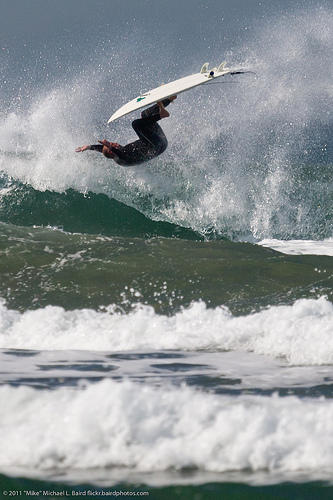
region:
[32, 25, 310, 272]
A man and a surboard falling from a tall wave.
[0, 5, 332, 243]
A large crashing wave.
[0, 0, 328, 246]
Water spraying in all directions.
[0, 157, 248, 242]
A wave tunnel forming.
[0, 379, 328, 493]
A wave rolling onto the shore.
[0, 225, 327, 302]
Choppy water between the waves.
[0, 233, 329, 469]
White water on the waves.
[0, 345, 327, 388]
Foam on the surface of the water.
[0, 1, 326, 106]
Blue skies above the water.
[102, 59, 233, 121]
An upside down surfboard falling from a wave.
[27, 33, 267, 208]
Man surfing in the ocean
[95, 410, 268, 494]
Foam in the water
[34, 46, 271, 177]
the surfboard is flipped upside down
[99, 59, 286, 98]
Surfboard is white and long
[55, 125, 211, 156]
the surfer is bald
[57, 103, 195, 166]
The surfer is wearing a wetsuit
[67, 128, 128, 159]
The man has his arm's outstretched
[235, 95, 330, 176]
Water is spraying from ocean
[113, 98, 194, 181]
Man's knees are bent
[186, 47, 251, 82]
Fins on bottom of surfboard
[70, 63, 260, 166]
A surfboarder is doing a flip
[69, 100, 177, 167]
The surfboarder is upside down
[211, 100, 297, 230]
The spray of the water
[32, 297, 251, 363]
Waves crashing against each other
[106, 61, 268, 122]
The bottom of the surfboard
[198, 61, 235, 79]
Talons on a surfboard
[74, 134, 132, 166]
The man's arms are outstretched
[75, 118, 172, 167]
The man's wetsuit is black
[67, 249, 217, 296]
The waves are sea green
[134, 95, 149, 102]
A green design on the surfboard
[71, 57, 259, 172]
man surfing in ocean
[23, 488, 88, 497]
name of photographer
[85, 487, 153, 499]
flickr web address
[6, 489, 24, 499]
numerical photograph year stamp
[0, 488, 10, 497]
white print copyright symbol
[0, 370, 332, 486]
white wave in ocean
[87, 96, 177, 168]
black wet suit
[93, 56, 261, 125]
white surfboard flipping over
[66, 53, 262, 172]
person crashing on a wave in the ocean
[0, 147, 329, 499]
green and blue ocean water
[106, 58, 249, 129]
white surfboard over man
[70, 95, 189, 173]
manin black wet suit surfing upside down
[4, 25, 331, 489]
white waves in water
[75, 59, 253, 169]
man on white surfboard surfing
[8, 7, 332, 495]
daytime sunny surfing beach scene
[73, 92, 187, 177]
barefoot surfer with arms outstretched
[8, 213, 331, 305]
gray green ocean water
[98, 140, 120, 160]
blond hair on bald head of man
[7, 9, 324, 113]
clear blue cloudless sky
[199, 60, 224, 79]
three small rudders on underside of surfboard